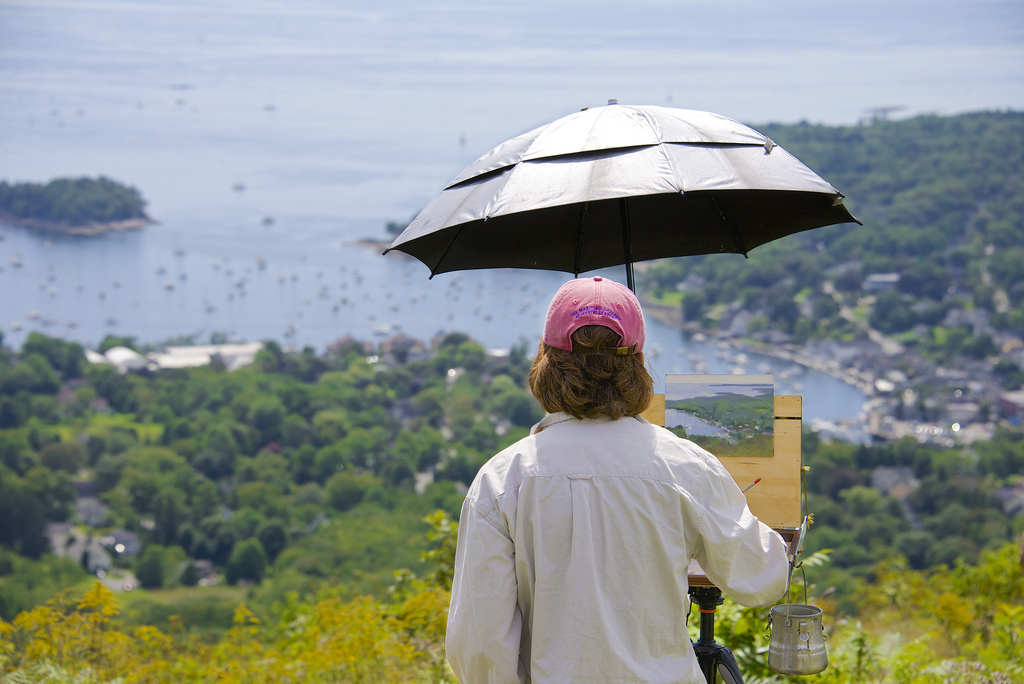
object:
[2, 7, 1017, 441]
water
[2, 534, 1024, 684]
weeds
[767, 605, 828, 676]
bucket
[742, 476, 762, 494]
pen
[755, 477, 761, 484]
tip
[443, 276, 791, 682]
girl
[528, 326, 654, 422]
hair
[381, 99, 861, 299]
umbrella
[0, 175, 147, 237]
island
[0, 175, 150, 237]
trees